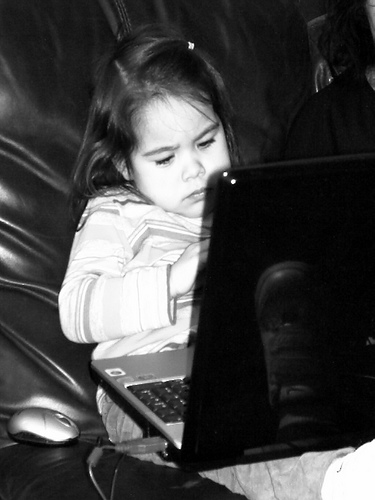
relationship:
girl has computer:
[60, 38, 256, 394] [84, 159, 372, 444]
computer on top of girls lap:
[84, 159, 372, 444] [92, 388, 245, 477]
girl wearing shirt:
[60, 38, 256, 394] [59, 190, 208, 361]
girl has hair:
[60, 38, 256, 394] [76, 23, 231, 207]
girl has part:
[60, 38, 256, 394] [108, 52, 135, 99]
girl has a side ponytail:
[60, 38, 256, 394] [133, 39, 224, 97]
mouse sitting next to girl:
[3, 408, 82, 446] [60, 38, 256, 394]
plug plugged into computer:
[92, 435, 171, 464] [84, 159, 372, 444]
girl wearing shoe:
[60, 38, 256, 394] [327, 441, 375, 499]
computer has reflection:
[84, 159, 372, 444] [259, 256, 332, 438]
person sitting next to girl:
[290, 7, 374, 154] [60, 38, 256, 394]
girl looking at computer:
[60, 38, 256, 394] [84, 159, 372, 444]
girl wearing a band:
[60, 38, 256, 394] [188, 42, 195, 51]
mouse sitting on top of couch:
[3, 408, 82, 446] [3, 4, 357, 329]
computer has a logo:
[84, 159, 372, 444] [106, 368, 128, 380]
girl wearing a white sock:
[60, 38, 256, 394] [327, 441, 375, 499]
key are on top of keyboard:
[136, 388, 152, 396] [124, 372, 237, 425]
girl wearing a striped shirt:
[60, 38, 256, 394] [59, 190, 208, 361]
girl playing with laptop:
[60, 38, 256, 394] [84, 159, 372, 444]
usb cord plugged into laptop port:
[84, 446, 108, 499] [129, 437, 174, 456]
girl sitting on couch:
[60, 38, 256, 394] [3, 4, 357, 329]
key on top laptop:
[136, 388, 156, 399] [84, 159, 372, 444]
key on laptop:
[136, 388, 156, 399] [84, 159, 372, 444]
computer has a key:
[84, 159, 372, 474] [136, 388, 156, 399]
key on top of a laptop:
[136, 388, 156, 399] [84, 159, 372, 444]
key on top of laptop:
[136, 388, 156, 399] [84, 159, 372, 444]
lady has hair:
[290, 7, 374, 154] [319, 17, 374, 83]